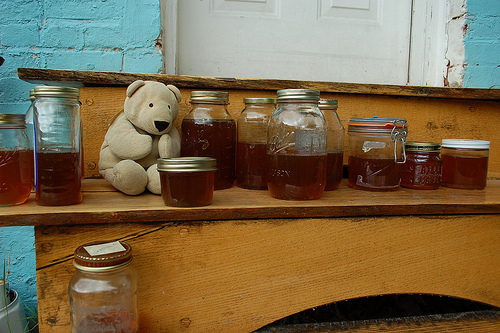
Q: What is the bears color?
A: Tan.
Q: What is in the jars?
A: Honey.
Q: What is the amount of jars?
A: 12.